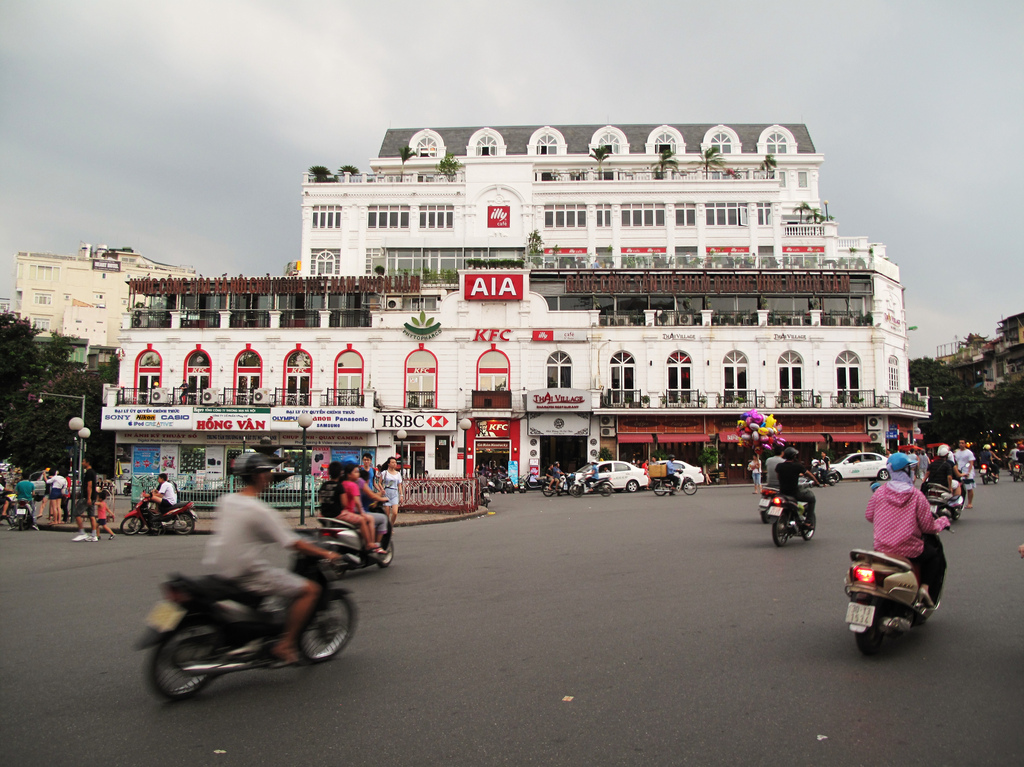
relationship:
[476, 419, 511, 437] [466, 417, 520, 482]
kfc sign over a doorway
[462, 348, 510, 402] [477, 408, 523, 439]
window over a kfc sign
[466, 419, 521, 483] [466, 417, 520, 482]
doorway to doorway